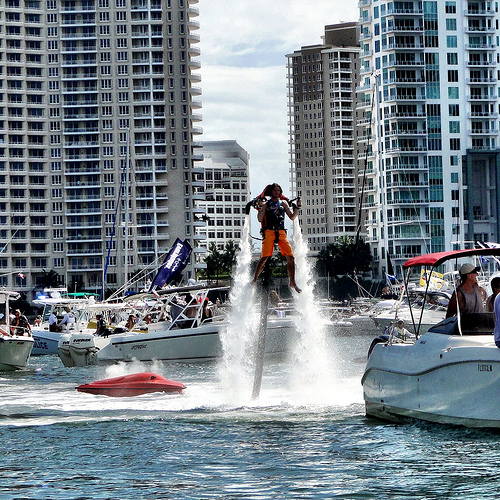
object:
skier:
[248, 182, 303, 293]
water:
[0, 344, 500, 500]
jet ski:
[74, 371, 187, 397]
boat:
[360, 245, 500, 430]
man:
[445, 262, 487, 318]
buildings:
[0, 0, 206, 299]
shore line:
[0, 284, 500, 322]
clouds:
[195, 0, 286, 131]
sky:
[190, 1, 370, 193]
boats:
[0, 335, 36, 372]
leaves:
[343, 234, 348, 245]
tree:
[315, 235, 374, 278]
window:
[396, 70, 416, 79]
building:
[358, 0, 500, 288]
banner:
[148, 237, 194, 293]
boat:
[68, 282, 231, 368]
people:
[492, 292, 500, 347]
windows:
[449, 103, 459, 116]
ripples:
[0, 426, 499, 498]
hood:
[401, 247, 499, 271]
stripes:
[111, 326, 293, 346]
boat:
[96, 318, 300, 365]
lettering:
[477, 363, 492, 371]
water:
[221, 215, 348, 402]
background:
[1, 0, 499, 498]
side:
[361, 343, 499, 427]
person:
[11, 309, 31, 337]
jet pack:
[258, 199, 286, 232]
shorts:
[260, 229, 294, 259]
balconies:
[388, 222, 423, 239]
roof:
[61, 292, 100, 297]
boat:
[25, 298, 96, 356]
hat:
[459, 263, 475, 275]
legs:
[254, 231, 275, 280]